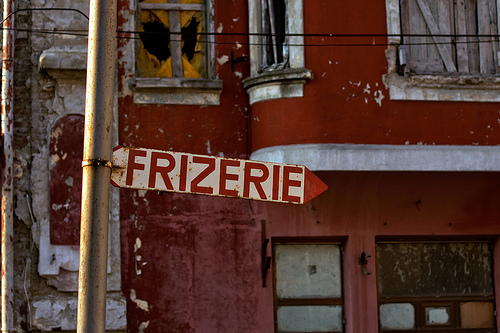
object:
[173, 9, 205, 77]
polythene material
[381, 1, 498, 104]
window frame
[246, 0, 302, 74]
window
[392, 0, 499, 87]
window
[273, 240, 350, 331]
window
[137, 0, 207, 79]
curtains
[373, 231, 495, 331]
window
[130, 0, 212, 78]
window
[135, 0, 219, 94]
wood frame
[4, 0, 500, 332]
building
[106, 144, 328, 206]
black shirt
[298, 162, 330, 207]
point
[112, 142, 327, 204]
horse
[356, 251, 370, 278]
light fixture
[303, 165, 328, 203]
red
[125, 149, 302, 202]
red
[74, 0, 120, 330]
pole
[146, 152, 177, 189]
letter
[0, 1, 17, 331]
pipe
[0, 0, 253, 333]
wall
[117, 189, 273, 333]
paint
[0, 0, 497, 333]
concrete wall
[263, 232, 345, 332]
door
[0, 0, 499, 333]
house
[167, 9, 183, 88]
wood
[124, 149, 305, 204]
letters